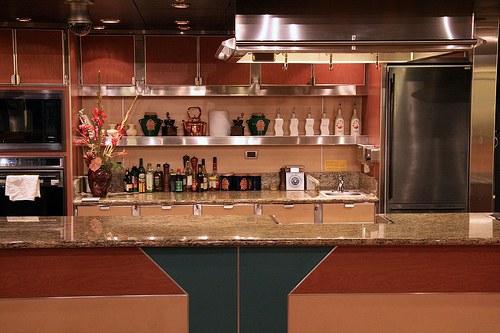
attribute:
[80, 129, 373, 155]
shelf — kitchen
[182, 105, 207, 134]
teapot — gold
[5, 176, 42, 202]
kitchen towel — white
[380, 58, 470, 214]
refrigerator — stainless steel, silver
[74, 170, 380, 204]
counter — light brown, marble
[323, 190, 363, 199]
sink — silver, small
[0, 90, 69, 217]
appliance — black, silver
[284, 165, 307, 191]
scale — white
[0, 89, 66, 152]
microwave — black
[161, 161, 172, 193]
pepper grinder — brown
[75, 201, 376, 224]
drawers — cream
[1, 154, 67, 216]
oven — black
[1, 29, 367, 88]
cabinets — cherrywood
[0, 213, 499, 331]
counter — large